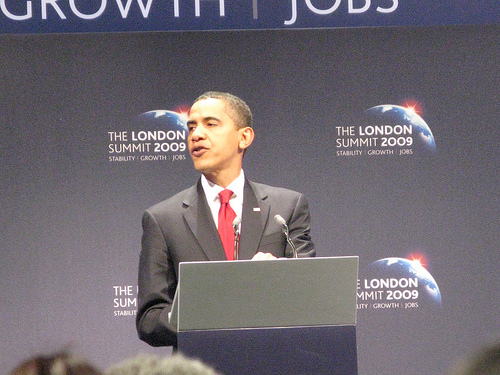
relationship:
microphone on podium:
[271, 211, 303, 259] [177, 236, 379, 373]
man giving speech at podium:
[140, 92, 322, 262] [83, 236, 464, 365]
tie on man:
[217, 189, 236, 261] [133, 90, 317, 359]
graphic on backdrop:
[312, 97, 454, 188] [7, 5, 492, 369]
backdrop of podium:
[7, 5, 492, 369] [173, 253, 362, 364]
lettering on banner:
[2, 2, 405, 19] [1, 0, 499, 35]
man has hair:
[133, 90, 317, 359] [190, 90, 255, 127]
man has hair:
[133, 90, 317, 359] [198, 90, 256, 127]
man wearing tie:
[133, 90, 317, 359] [215, 187, 235, 262]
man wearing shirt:
[133, 90, 317, 359] [198, 170, 245, 235]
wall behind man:
[47, 65, 442, 370] [133, 90, 317, 359]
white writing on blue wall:
[337, 116, 410, 147] [49, 160, 116, 253]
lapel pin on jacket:
[249, 202, 265, 214] [137, 179, 312, 336]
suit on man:
[137, 168, 317, 347] [116, 67, 363, 349]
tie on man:
[217, 189, 236, 261] [116, 67, 363, 349]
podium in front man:
[167, 254, 372, 370] [133, 90, 317, 359]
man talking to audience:
[133, 90, 317, 359] [0, 340, 499, 373]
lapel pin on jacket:
[252, 207, 260, 211] [135, 170, 315, 346]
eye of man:
[207, 120, 216, 126] [119, 82, 346, 336]